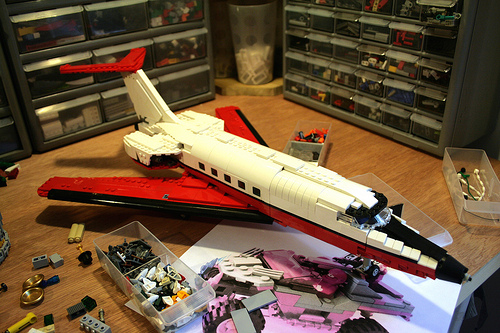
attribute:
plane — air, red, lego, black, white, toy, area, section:
[31, 19, 469, 291]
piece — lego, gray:
[54, 223, 90, 251]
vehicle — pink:
[225, 244, 375, 324]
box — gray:
[279, 3, 499, 167]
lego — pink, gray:
[300, 127, 338, 148]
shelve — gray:
[259, 6, 482, 131]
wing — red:
[30, 160, 179, 235]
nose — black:
[370, 193, 472, 313]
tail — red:
[52, 34, 172, 99]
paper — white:
[425, 297, 460, 328]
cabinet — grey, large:
[10, 20, 234, 170]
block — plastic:
[143, 276, 166, 286]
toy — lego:
[140, 120, 353, 244]